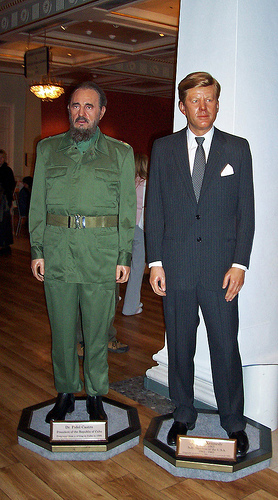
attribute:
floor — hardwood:
[1, 232, 275, 499]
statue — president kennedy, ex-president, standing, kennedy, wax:
[143, 69, 250, 463]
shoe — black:
[165, 421, 189, 448]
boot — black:
[45, 392, 76, 423]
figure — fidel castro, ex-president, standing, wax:
[25, 78, 134, 421]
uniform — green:
[24, 135, 138, 398]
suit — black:
[143, 131, 255, 434]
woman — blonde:
[123, 149, 152, 314]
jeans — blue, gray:
[120, 225, 144, 311]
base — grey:
[15, 393, 144, 462]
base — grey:
[143, 410, 274, 482]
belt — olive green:
[45, 211, 119, 227]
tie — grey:
[188, 135, 208, 199]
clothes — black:
[0, 163, 16, 244]